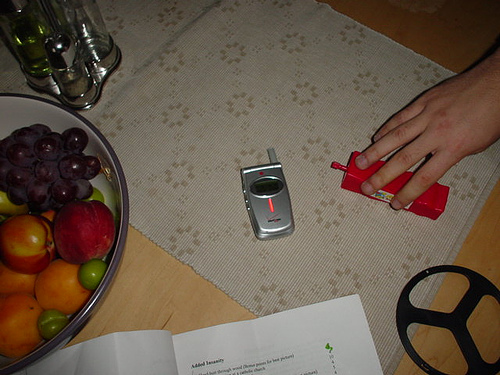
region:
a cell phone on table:
[233, 142, 300, 243]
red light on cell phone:
[236, 140, 299, 245]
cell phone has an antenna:
[227, 136, 293, 196]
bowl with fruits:
[0, 87, 134, 374]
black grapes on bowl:
[3, 120, 108, 215]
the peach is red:
[45, 194, 120, 272]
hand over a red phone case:
[322, 63, 497, 223]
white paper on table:
[79, 281, 399, 373]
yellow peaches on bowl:
[0, 260, 85, 353]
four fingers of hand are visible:
[353, 88, 451, 215]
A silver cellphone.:
[233, 145, 300, 244]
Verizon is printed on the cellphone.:
[229, 144, 297, 244]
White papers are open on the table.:
[55, 293, 390, 374]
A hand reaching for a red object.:
[322, 43, 499, 245]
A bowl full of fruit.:
[3, 93, 128, 373]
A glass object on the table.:
[9, 2, 124, 108]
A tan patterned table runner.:
[107, 0, 499, 370]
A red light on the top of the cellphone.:
[239, 148, 304, 244]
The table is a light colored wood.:
[5, 5, 490, 373]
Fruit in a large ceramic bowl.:
[3, 93, 136, 372]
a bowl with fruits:
[2, 87, 132, 372]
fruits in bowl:
[2, 90, 133, 374]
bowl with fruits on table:
[3, 87, 133, 374]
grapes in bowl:
[1, 119, 105, 212]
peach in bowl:
[49, 197, 116, 267]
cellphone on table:
[236, 143, 297, 245]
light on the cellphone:
[266, 195, 277, 213]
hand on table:
[351, 83, 499, 215]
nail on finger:
[354, 152, 371, 169]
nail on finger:
[360, 181, 376, 196]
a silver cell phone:
[223, 112, 315, 262]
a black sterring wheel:
[383, 250, 499, 372]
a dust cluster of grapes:
[0, 115, 112, 214]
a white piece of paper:
[89, 269, 380, 373]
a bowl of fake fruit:
[2, 92, 135, 363]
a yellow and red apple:
[0, 212, 51, 284]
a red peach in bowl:
[48, 187, 125, 272]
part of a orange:
[43, 265, 67, 307]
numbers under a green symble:
[326, 340, 339, 373]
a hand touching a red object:
[301, 91, 481, 239]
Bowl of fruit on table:
[1, 91, 129, 374]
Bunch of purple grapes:
[0, 122, 100, 214]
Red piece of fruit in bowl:
[51, 198, 117, 264]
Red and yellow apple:
[0, 213, 57, 274]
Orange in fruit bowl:
[33, 257, 93, 315]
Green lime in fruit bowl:
[75, 257, 107, 291]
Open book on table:
[10, 293, 384, 373]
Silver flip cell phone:
[237, 145, 297, 242]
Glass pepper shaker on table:
[39, 28, 96, 108]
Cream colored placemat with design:
[1, 0, 498, 372]